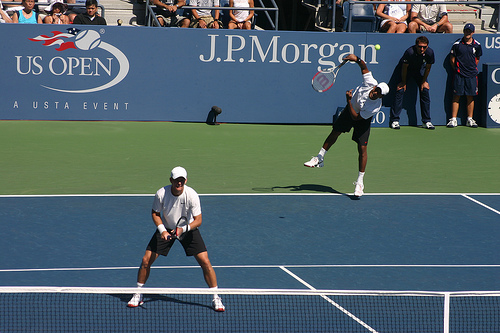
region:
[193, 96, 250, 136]
black object at edge of court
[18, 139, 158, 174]
green asphalt on the court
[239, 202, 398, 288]
blue tennis court on the asphalt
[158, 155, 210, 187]
white cap on player's head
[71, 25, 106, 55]
white ball on log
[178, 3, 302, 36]
blue railing in the stands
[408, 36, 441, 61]
sun glasses on man's face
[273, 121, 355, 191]
man's leg raised off the ground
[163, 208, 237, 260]
tennis racket in player's hand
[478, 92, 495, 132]
portion of large white clock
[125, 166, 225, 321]
MAN PLAYING TENNIS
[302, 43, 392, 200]
MAN SERVING A TENNIS BALL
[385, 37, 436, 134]
MAN WITH BOTH HIS HANDS ON HIS KNEES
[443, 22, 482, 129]
MAN WITH HIS ARMS BEHIND HIS BACK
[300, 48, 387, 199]
MAN HOLDING A TENNIS RACQUET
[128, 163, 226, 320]
MAN WEARING A WHITE BASEBALL CAP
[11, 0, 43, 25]
WOMAN WEARING A LIGHT BLUE TOP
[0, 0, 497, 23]
SPECTATORS WATCHING A TENNIS MATCH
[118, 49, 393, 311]
TWO MEN PARTICIPATING IN A TENNIS MATCH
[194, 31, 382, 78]
J.P. MORGAN DISPLAYED IN WHITE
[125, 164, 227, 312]
man standing on a tennis court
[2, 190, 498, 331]
tennis court is blue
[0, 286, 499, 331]
net in front of man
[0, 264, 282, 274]
white line on tennis court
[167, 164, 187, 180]
man wearing a white cap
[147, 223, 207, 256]
man wearing black shorts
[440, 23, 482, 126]
man standing next to wall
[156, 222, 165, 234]
white band on arm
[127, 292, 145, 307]
man wearing white shoes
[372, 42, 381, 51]
yellow tennis ball over tennis court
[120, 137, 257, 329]
Man on the court.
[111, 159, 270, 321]
Man playing a game of tennis.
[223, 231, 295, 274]
White line on the court.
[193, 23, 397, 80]
Advertising on the back drop.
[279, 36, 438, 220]
Man jumping in the air.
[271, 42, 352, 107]
Racket in the man's hand.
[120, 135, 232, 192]
White hat on the man's head.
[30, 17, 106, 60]
Red, white, and blue logo.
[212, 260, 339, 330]
Net in the foreground.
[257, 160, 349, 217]
Shadow on the ground.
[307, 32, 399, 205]
The man is playing tennis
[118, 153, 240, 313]
Man standing on the court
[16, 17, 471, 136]
The wall is blue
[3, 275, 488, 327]
The net is white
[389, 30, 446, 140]
Man leaning against the wall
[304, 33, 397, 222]
The man is hitting the ball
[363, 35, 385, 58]
The ball is yellow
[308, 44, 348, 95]
The tennis racket is red, white and black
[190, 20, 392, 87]
J.P. Morgan on the wall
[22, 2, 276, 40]
People sitting in the stands